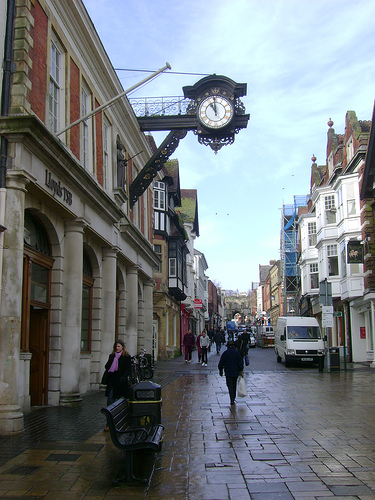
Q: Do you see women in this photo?
A: Yes, there is a woman.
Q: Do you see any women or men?
A: Yes, there is a woman.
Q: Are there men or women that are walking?
A: Yes, the woman is walking.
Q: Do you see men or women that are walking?
A: Yes, the woman is walking.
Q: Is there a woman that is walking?
A: Yes, there is a woman that is walking.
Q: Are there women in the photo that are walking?
A: Yes, there is a woman that is walking.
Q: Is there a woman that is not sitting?
A: Yes, there is a woman that is walking.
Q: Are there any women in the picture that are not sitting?
A: Yes, there is a woman that is walking.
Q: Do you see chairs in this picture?
A: No, there are no chairs.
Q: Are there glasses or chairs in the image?
A: No, there are no chairs or glasses.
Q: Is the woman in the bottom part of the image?
A: Yes, the woman is in the bottom of the image.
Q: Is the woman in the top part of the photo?
A: No, the woman is in the bottom of the image.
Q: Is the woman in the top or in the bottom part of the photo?
A: The woman is in the bottom of the image.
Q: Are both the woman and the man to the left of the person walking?
A: Yes, both the woman and the man are walking.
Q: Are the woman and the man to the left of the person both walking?
A: Yes, both the woman and the man are walking.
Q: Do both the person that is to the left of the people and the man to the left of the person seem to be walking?
A: Yes, both the woman and the man are walking.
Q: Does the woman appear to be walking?
A: Yes, the woman is walking.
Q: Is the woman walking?
A: Yes, the woman is walking.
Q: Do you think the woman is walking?
A: Yes, the woman is walking.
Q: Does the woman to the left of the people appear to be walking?
A: Yes, the woman is walking.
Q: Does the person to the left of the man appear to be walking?
A: Yes, the woman is walking.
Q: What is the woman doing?
A: The woman is walking.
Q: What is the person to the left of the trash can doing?
A: The woman is walking.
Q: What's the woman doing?
A: The woman is walking.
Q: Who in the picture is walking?
A: The woman is walking.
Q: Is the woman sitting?
A: No, the woman is walking.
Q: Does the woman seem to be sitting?
A: No, the woman is walking.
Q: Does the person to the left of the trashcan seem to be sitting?
A: No, the woman is walking.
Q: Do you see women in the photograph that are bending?
A: No, there is a woman but she is walking.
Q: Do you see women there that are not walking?
A: No, there is a woman but she is walking.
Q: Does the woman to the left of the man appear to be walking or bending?
A: The woman is walking.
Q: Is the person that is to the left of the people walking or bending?
A: The woman is walking.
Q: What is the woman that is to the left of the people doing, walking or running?
A: The woman is walking.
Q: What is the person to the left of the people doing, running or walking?
A: The woman is walking.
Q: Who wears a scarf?
A: The woman wears a scarf.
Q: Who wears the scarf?
A: The woman wears a scarf.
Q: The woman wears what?
A: The woman wears a scarf.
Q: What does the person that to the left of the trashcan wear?
A: The woman wears a scarf.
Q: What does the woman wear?
A: The woman wears a scarf.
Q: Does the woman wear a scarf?
A: Yes, the woman wears a scarf.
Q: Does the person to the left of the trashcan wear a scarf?
A: Yes, the woman wears a scarf.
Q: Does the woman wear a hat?
A: No, the woman wears a scarf.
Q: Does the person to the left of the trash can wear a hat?
A: No, the woman wears a scarf.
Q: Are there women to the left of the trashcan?
A: Yes, there is a woman to the left of the trashcan.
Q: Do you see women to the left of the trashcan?
A: Yes, there is a woman to the left of the trashcan.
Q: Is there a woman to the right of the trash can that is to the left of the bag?
A: No, the woman is to the left of the trash can.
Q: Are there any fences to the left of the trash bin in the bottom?
A: No, there is a woman to the left of the garbage can.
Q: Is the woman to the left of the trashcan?
A: Yes, the woman is to the left of the trashcan.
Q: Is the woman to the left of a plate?
A: No, the woman is to the left of the trashcan.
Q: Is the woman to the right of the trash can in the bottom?
A: No, the woman is to the left of the trash bin.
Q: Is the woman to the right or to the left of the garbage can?
A: The woman is to the left of the garbage can.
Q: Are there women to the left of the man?
A: Yes, there is a woman to the left of the man.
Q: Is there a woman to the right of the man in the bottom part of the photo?
A: No, the woman is to the left of the man.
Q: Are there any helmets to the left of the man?
A: No, there is a woman to the left of the man.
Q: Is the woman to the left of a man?
A: Yes, the woman is to the left of a man.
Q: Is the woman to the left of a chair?
A: No, the woman is to the left of a man.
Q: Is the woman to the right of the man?
A: No, the woman is to the left of the man.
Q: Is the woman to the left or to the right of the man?
A: The woman is to the left of the man.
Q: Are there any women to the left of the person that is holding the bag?
A: Yes, there is a woman to the left of the person.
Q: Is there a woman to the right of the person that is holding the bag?
A: No, the woman is to the left of the person.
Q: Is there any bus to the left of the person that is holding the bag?
A: No, there is a woman to the left of the person.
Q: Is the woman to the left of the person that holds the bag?
A: Yes, the woman is to the left of the person.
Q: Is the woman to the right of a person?
A: No, the woman is to the left of a person.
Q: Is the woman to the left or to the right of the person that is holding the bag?
A: The woman is to the left of the person.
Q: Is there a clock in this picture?
A: Yes, there is a clock.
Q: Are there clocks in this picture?
A: Yes, there is a clock.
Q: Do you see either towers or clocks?
A: Yes, there is a clock.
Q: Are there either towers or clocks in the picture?
A: Yes, there is a clock.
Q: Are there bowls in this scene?
A: No, there are no bowls.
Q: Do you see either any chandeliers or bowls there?
A: No, there are no bowls or chandeliers.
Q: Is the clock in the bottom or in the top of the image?
A: The clock is in the top of the image.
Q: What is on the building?
A: The clock is on the building.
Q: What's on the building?
A: The clock is on the building.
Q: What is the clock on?
A: The clock is on the building.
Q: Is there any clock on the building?
A: Yes, there is a clock on the building.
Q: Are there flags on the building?
A: No, there is a clock on the building.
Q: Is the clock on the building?
A: Yes, the clock is on the building.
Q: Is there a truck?
A: Yes, there is a truck.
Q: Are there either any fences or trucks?
A: Yes, there is a truck.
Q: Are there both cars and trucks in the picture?
A: No, there is a truck but no cars.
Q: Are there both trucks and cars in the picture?
A: No, there is a truck but no cars.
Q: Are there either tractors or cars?
A: No, there are no cars or tractors.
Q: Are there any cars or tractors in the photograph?
A: No, there are no cars or tractors.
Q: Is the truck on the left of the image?
A: No, the truck is on the right of the image.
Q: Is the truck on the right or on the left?
A: The truck is on the right of the image.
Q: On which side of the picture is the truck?
A: The truck is on the right of the image.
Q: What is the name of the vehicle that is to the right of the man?
A: The vehicle is a truck.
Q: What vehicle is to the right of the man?
A: The vehicle is a truck.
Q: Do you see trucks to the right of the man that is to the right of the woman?
A: Yes, there is a truck to the right of the man.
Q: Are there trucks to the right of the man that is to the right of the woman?
A: Yes, there is a truck to the right of the man.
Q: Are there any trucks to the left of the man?
A: No, the truck is to the right of the man.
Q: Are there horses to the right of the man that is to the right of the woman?
A: No, there is a truck to the right of the man.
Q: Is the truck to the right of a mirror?
A: No, the truck is to the right of the man.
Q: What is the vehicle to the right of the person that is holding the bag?
A: The vehicle is a truck.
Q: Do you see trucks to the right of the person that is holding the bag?
A: Yes, there is a truck to the right of the person.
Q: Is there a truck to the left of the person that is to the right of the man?
A: No, the truck is to the right of the person.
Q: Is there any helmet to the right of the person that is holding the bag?
A: No, there is a truck to the right of the person.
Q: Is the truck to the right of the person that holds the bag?
A: Yes, the truck is to the right of the person.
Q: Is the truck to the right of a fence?
A: No, the truck is to the right of the person.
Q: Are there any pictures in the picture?
A: No, there are no pictures.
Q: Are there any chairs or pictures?
A: No, there are no pictures or chairs.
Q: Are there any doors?
A: Yes, there is a door.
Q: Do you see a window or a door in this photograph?
A: Yes, there is a door.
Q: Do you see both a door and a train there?
A: No, there is a door but no trains.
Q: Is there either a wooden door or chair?
A: Yes, there is a wood door.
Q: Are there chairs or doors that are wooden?
A: Yes, the door is wooden.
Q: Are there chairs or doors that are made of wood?
A: Yes, the door is made of wood.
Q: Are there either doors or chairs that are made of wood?
A: Yes, the door is made of wood.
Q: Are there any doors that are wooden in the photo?
A: Yes, there is a wood door.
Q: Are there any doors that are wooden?
A: Yes, there is a door that is wooden.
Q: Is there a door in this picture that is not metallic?
A: Yes, there is a wooden door.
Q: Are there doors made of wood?
A: Yes, there is a door that is made of wood.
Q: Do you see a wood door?
A: Yes, there is a door that is made of wood.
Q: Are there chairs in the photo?
A: No, there are no chairs.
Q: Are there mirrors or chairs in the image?
A: No, there are no chairs or mirrors.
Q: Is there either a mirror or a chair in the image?
A: No, there are no chairs or mirrors.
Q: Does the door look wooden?
A: Yes, the door is wooden.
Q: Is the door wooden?
A: Yes, the door is wooden.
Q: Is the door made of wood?
A: Yes, the door is made of wood.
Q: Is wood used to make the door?
A: Yes, the door is made of wood.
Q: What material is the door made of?
A: The door is made of wood.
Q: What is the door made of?
A: The door is made of wood.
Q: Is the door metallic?
A: No, the door is wooden.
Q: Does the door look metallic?
A: No, the door is wooden.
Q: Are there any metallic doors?
A: No, there is a door but it is wooden.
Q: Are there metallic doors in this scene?
A: No, there is a door but it is wooden.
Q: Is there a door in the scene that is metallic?
A: No, there is a door but it is wooden.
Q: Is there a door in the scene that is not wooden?
A: No, there is a door but it is wooden.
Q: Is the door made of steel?
A: No, the door is made of wood.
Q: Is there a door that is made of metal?
A: No, there is a door but it is made of wood.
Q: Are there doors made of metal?
A: No, there is a door but it is made of wood.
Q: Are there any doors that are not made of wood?
A: No, there is a door but it is made of wood.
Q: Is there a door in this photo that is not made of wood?
A: No, there is a door but it is made of wood.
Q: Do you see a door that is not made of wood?
A: No, there is a door but it is made of wood.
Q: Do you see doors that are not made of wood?
A: No, there is a door but it is made of wood.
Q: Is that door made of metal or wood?
A: The door is made of wood.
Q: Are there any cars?
A: No, there are no cars.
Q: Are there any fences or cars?
A: No, there are no cars or fences.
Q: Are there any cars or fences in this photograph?
A: No, there are no cars or fences.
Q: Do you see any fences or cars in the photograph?
A: No, there are no cars or fences.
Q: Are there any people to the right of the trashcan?
A: Yes, there are people to the right of the trashcan.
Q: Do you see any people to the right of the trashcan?
A: Yes, there are people to the right of the trashcan.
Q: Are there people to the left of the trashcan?
A: No, the people are to the right of the trashcan.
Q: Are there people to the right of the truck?
A: No, the people are to the left of the truck.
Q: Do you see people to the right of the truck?
A: No, the people are to the left of the truck.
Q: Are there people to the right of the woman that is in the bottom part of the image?
A: Yes, there are people to the right of the woman.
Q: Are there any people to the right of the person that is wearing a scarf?
A: Yes, there are people to the right of the woman.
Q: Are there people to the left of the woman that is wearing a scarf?
A: No, the people are to the right of the woman.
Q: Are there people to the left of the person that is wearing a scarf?
A: No, the people are to the right of the woman.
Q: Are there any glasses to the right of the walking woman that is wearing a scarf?
A: No, there are people to the right of the woman.